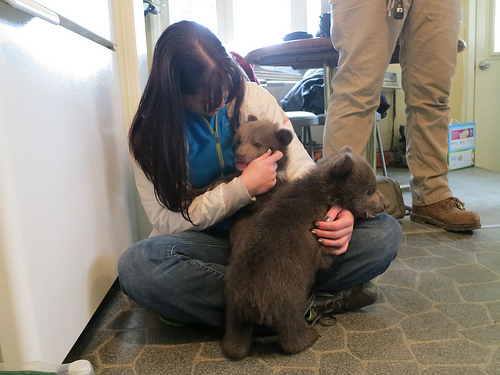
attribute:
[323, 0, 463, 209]
trousers — tan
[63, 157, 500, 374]
floor — marble, stone, grey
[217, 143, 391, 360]
bear — baby, cub, playing, brown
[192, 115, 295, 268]
bear — baby, cub, playing, brown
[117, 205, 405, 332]
jeans — blue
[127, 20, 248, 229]
hair — brown, black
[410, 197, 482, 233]
boot — brown, work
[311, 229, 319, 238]
fingernail — painted, silvery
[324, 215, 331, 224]
fingernail — painted, silvery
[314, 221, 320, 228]
fingernail — painted, silvery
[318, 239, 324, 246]
fingernail — painted, silvery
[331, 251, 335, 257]
fingernail — painted, silvery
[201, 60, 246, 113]
bangs — brown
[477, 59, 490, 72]
doorknob — silver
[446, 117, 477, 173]
box — litter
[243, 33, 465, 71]
table — small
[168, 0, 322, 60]
window — open